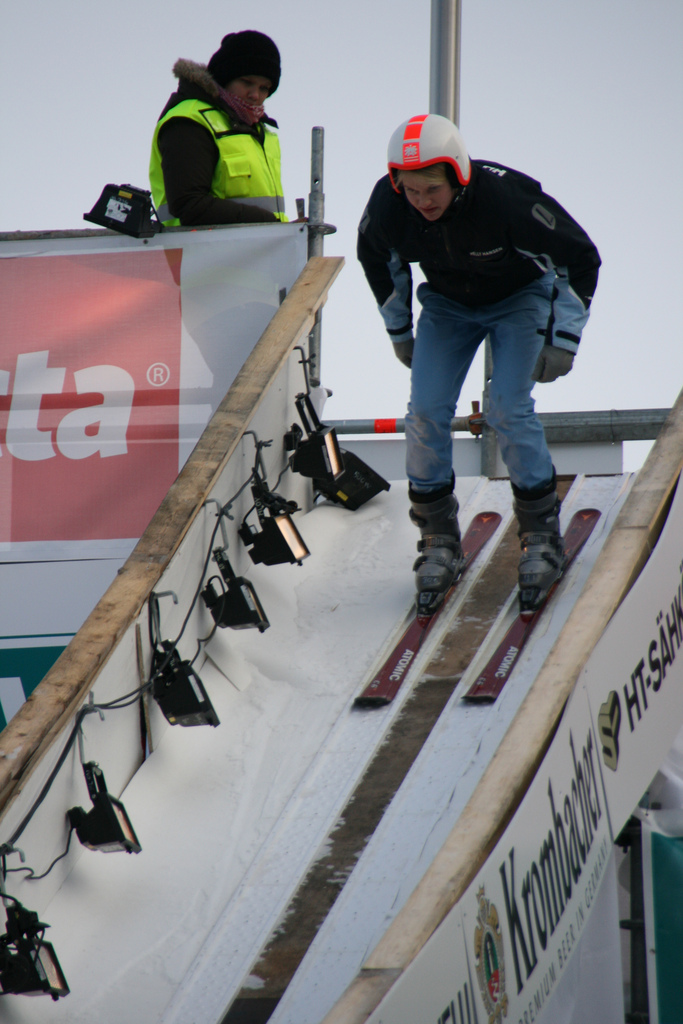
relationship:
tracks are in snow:
[229, 692, 486, 990] [109, 664, 458, 1016]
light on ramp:
[277, 491, 324, 585] [180, 423, 387, 848]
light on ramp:
[277, 491, 324, 585] [202, 329, 644, 1021]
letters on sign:
[478, 719, 609, 1021] [466, 732, 622, 995]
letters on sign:
[509, 821, 554, 927] [424, 812, 653, 982]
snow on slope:
[240, 493, 359, 864] [62, 621, 471, 982]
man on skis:
[435, 180, 610, 438] [348, 500, 608, 716]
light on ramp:
[277, 491, 324, 585] [4, 397, 654, 1001]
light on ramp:
[277, 490, 324, 584] [142, 384, 502, 843]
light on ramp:
[277, 491, 324, 585] [5, 253, 663, 1021]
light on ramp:
[277, 491, 324, 585] [79, 427, 518, 839]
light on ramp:
[277, 491, 324, 585] [244, 560, 569, 848]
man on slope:
[354, 109, 602, 630] [231, 489, 496, 775]